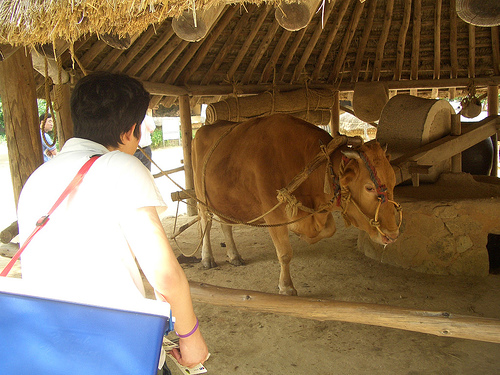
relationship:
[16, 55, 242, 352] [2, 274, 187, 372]
person with a bag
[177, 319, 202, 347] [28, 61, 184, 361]
band on person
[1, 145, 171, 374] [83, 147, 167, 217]
bag on shoulder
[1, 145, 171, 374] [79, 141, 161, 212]
bag on shoulder